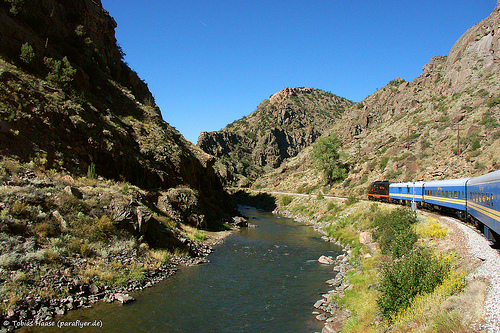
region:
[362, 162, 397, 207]
red and black locomotive pulling cars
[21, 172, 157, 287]
rocks and scrub brush by stream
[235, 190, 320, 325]
small stream near train tracks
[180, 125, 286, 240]
shadow of rocky hill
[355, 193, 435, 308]
small green bushes by tracks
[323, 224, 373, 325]
rocks on shore of stream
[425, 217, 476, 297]
tiny yellow bushes by tracks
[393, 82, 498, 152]
hill with green bushes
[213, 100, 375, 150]
medium grassy hill in distance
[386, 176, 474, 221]
blue and white passenger cars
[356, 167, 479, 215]
blue train with yellow stripe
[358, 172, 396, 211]
black and orange train engine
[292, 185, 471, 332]
bank with several green bushes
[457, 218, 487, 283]
rocks next to train track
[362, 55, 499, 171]
red rock hill above train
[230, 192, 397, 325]
small river next to train tracks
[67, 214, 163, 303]
rocks and grass on bank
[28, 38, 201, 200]
rocks casting shadow on the hill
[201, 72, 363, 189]
mountain behind the hill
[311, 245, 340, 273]
small rocks in the river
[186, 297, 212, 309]
Small section of blue and green murky water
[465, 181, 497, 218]
Blue and yellow train in motion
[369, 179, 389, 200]
Orange and black front train in motion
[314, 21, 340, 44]
A clear blue sky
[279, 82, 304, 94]
Small section of the top of the mountain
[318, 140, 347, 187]
Green tree on the hill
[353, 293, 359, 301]
Small patch of green grass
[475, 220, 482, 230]
One of the many wheels on the train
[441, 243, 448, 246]
Small patch of dirt next to the train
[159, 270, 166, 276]
A few rocks next to the water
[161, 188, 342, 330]
a dark green stream between mountains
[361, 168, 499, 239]
a curving train on tracks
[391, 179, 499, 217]
three blue and white train cars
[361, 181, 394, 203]
a black and orange front of a train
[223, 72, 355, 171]
a big tree covered mountain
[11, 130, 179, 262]
the rocky bottom of a mountainside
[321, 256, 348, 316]
small stones and rocks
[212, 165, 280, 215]
shadows cast by nearby trees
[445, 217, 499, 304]
gray gravel along the railroad tracks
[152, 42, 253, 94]
a completely clear blue sky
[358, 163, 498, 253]
THE TRAIN IS BLUE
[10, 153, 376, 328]
THE RIVER IS CURED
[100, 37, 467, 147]
THE SKY IS CLEAR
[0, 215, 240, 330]
THE WATER HAS ROCKS IN IT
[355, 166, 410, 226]
THE FRONT OF THE TRAIN IS BLACK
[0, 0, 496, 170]
THE MOUNTAINS ARE ROCKY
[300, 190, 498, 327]
THE BUSHES ARE GREEN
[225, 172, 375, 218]
THE TRAIN TRACK IS LONG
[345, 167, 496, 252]
THE TRAIN IS MOVING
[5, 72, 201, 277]
THE MOUNTAIN IS STEEP